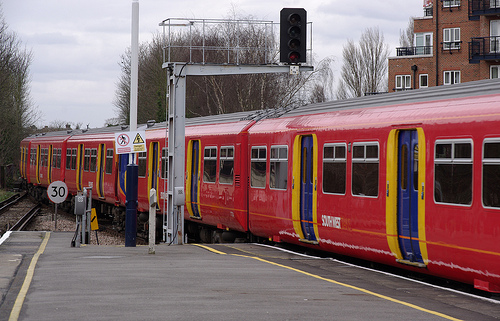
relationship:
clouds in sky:
[23, 17, 136, 93] [50, 24, 160, 83]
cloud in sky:
[2, 24, 92, 46] [3, 1, 433, 124]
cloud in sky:
[81, 7, 241, 44] [3, 1, 433, 124]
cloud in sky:
[297, 4, 428, 49] [3, 1, 433, 124]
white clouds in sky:
[34, 17, 125, 121] [3, 1, 433, 124]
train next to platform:
[19, 81, 496, 292] [5, 223, 474, 319]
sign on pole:
[115, 130, 132, 154] [120, 2, 140, 247]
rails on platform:
[10, 203, 47, 228] [15, 230, 415, 319]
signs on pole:
[110, 122, 153, 157] [124, 3, 147, 246]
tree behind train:
[142, 29, 243, 96] [13, 94, 480, 226]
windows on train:
[320, 136, 385, 211] [231, 108, 471, 268]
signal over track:
[207, 7, 378, 115] [257, 237, 499, 302]